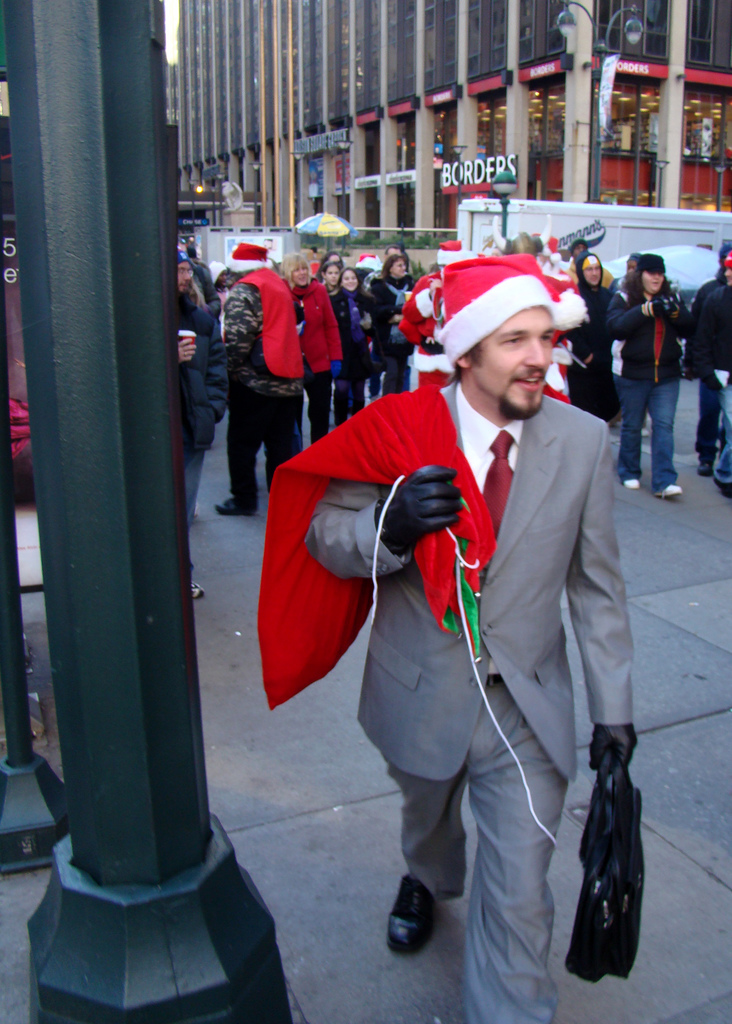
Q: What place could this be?
A: It is a sidewalk.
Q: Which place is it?
A: It is a sidewalk.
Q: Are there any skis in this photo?
A: No, there are no skis.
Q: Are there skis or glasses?
A: No, there are no skis or glasses.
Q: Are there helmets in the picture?
A: No, there are no helmets.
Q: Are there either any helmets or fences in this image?
A: No, there are no helmets or fences.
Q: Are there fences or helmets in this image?
A: No, there are no helmets or fences.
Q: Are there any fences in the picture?
A: No, there are no fences.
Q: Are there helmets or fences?
A: No, there are no fences or helmets.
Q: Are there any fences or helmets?
A: No, there are no fences or helmets.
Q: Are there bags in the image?
A: Yes, there is a bag.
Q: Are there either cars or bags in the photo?
A: Yes, there is a bag.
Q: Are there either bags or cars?
A: Yes, there is a bag.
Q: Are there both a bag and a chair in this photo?
A: No, there is a bag but no chairs.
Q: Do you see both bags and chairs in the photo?
A: No, there is a bag but no chairs.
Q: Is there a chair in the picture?
A: No, there are no chairs.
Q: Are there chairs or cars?
A: No, there are no chairs or cars.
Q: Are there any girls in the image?
A: No, there are no girls.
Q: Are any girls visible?
A: No, there are no girls.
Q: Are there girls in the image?
A: No, there are no girls.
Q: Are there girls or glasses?
A: No, there are no girls or glasses.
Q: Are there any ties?
A: Yes, there is a tie.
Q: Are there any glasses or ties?
A: Yes, there is a tie.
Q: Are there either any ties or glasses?
A: Yes, there is a tie.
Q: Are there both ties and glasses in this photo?
A: No, there is a tie but no glasses.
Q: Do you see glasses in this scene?
A: No, there are no glasses.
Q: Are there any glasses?
A: No, there are no glasses.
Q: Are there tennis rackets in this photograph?
A: No, there are no tennis rackets.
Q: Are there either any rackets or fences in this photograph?
A: No, there are no rackets or fences.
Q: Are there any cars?
A: No, there are no cars.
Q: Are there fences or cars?
A: No, there are no cars or fences.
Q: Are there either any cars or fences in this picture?
A: No, there are no cars or fences.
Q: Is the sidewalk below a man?
A: Yes, the sidewalk is below a man.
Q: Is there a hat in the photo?
A: Yes, there is a hat.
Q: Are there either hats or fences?
A: Yes, there is a hat.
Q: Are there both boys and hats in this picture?
A: No, there is a hat but no boys.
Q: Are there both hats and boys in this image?
A: No, there is a hat but no boys.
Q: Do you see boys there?
A: No, there are no boys.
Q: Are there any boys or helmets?
A: No, there are no boys or helmets.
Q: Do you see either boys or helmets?
A: No, there are no boys or helmets.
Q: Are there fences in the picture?
A: No, there are no fences.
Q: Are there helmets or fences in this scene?
A: No, there are no fences or helmets.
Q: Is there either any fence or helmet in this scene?
A: No, there are no fences or helmets.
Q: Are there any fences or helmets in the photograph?
A: No, there are no fences or helmets.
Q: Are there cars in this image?
A: No, there are no cars.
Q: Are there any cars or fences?
A: No, there are no cars or fences.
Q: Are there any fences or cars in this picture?
A: No, there are no cars or fences.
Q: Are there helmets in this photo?
A: No, there are no helmets.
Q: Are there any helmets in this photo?
A: No, there are no helmets.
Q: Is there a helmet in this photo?
A: No, there are no helmets.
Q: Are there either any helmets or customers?
A: No, there are no helmets or customers.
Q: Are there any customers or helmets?
A: No, there are no helmets or customers.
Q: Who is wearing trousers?
A: The man is wearing trousers.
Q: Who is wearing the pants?
A: The man is wearing trousers.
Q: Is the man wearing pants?
A: Yes, the man is wearing pants.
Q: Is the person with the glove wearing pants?
A: Yes, the man is wearing pants.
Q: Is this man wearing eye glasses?
A: No, the man is wearing pants.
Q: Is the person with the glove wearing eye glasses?
A: No, the man is wearing pants.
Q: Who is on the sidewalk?
A: The man is on the sidewalk.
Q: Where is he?
A: The man is on the sidewalk.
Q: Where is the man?
A: The man is on the sidewalk.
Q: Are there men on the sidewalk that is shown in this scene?
A: Yes, there is a man on the sidewalk.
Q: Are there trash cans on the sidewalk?
A: No, there is a man on the sidewalk.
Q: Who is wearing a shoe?
A: The man is wearing a shoe.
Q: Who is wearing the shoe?
A: The man is wearing a shoe.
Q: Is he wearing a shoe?
A: Yes, the man is wearing a shoe.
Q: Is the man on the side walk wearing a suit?
A: No, the man is wearing a shoe.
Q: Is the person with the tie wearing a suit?
A: No, the man is wearing a shoe.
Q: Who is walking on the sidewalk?
A: The man is walking on the sidewalk.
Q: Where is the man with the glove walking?
A: The man is walking on the sidewalk.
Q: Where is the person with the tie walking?
A: The man is walking on the sidewalk.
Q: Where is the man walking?
A: The man is walking on the sidewalk.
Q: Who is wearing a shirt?
A: The man is wearing a shirt.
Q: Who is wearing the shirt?
A: The man is wearing a shirt.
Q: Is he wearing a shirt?
A: Yes, the man is wearing a shirt.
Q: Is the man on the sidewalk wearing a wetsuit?
A: No, the man is wearing a shirt.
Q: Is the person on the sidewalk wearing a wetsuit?
A: No, the man is wearing a shirt.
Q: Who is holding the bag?
A: The man is holding the bag.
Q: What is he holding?
A: The man is holding the bag.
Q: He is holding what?
A: The man is holding the bag.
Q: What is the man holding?
A: The man is holding the bag.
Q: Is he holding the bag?
A: Yes, the man is holding the bag.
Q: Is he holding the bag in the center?
A: Yes, the man is holding the bag.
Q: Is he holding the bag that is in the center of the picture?
A: Yes, the man is holding the bag.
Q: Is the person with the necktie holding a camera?
A: No, the man is holding the bag.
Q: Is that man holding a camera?
A: No, the man is holding the bag.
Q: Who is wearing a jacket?
A: The man is wearing a jacket.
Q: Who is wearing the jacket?
A: The man is wearing a jacket.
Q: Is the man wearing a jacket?
A: Yes, the man is wearing a jacket.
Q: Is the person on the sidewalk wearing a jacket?
A: Yes, the man is wearing a jacket.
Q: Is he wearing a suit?
A: No, the man is wearing a jacket.